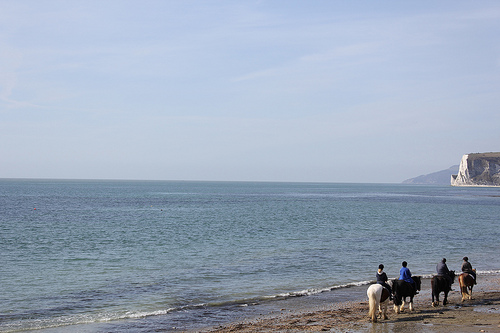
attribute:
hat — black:
[378, 261, 385, 270]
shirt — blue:
[397, 266, 413, 280]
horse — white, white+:
[364, 277, 400, 324]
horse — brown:
[389, 274, 424, 312]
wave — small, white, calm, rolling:
[93, 265, 499, 324]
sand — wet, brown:
[197, 277, 499, 332]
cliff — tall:
[448, 172, 460, 188]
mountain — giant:
[450, 150, 500, 192]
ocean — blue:
[2, 179, 498, 332]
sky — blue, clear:
[2, 2, 499, 185]